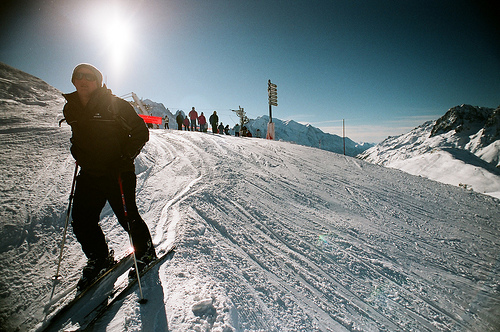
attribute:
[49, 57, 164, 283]
man — skiing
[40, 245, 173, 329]
skis — black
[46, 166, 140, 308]
ski poles — red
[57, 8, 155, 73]
sun — shining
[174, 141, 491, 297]
snow — white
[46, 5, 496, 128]
sky — blue